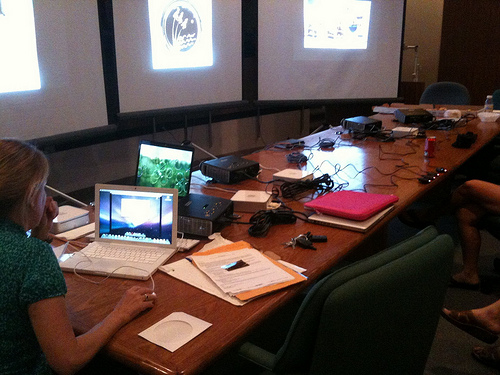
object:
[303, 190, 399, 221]
red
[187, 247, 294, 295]
paper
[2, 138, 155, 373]
woman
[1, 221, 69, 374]
green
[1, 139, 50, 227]
blonde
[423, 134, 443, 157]
red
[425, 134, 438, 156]
aluminum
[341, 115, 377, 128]
black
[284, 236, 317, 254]
key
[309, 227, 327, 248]
fob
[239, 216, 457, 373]
empty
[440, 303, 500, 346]
sandal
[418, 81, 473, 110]
edge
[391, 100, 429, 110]
edge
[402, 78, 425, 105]
table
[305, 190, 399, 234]
edge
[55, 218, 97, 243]
part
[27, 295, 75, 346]
part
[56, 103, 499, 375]
large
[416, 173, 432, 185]
gadget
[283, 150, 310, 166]
gadget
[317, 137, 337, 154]
gadget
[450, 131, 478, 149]
gadget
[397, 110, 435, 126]
gadget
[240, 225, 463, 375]
chair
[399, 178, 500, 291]
person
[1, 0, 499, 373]
room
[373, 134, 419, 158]
wire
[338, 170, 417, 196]
wire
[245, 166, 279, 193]
wire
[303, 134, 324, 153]
wire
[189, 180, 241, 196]
wire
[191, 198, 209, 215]
black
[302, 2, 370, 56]
image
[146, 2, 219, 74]
image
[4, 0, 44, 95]
image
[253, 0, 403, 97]
screen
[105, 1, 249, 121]
screen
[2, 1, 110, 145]
screen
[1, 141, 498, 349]
meeting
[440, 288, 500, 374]
woman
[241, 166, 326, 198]
portion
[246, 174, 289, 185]
cable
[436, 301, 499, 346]
foot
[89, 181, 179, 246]
monitor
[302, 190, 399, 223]
book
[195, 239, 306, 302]
folder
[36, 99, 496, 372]
table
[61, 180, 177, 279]
laptop